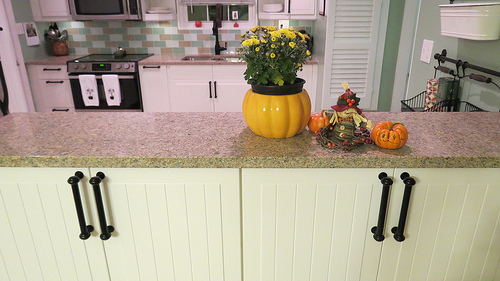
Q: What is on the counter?
A: Fall decorations.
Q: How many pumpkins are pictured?
A: Three.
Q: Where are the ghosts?
A: On the towels hanging on the oven.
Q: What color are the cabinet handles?
A: Black.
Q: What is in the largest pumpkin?
A: Flowers.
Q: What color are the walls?
A: Light green.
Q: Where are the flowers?
A: In the pumpkin.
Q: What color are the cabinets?
A: White.